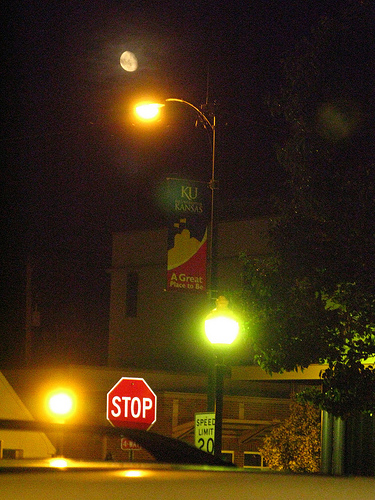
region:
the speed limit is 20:
[173, 407, 219, 471]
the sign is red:
[91, 376, 186, 477]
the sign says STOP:
[104, 354, 158, 444]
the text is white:
[106, 390, 170, 436]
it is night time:
[38, 127, 267, 487]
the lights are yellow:
[195, 289, 279, 388]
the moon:
[117, 40, 151, 73]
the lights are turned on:
[85, 75, 309, 406]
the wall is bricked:
[181, 403, 200, 420]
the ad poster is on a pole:
[159, 168, 221, 300]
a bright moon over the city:
[96, 37, 154, 74]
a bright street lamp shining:
[44, 392, 82, 467]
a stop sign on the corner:
[111, 365, 161, 446]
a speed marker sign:
[186, 401, 222, 455]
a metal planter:
[317, 414, 366, 481]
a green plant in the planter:
[307, 387, 357, 412]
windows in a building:
[236, 442, 267, 467]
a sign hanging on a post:
[165, 177, 219, 295]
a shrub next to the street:
[259, 410, 313, 471]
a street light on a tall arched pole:
[116, 89, 226, 151]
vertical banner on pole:
[159, 170, 216, 306]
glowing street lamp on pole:
[200, 302, 248, 356]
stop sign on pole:
[104, 373, 164, 456]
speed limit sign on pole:
[188, 406, 218, 458]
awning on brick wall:
[229, 415, 274, 445]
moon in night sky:
[108, 42, 144, 79]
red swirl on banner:
[163, 240, 208, 296]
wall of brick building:
[247, 405, 275, 414]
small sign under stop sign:
[113, 435, 146, 452]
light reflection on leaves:
[255, 335, 283, 373]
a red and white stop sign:
[104, 375, 158, 436]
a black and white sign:
[192, 411, 218, 457]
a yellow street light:
[201, 295, 243, 346]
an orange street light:
[36, 380, 87, 425]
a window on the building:
[121, 268, 141, 319]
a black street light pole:
[159, 93, 226, 466]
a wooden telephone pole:
[20, 249, 37, 371]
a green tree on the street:
[223, 0, 374, 437]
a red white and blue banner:
[163, 175, 211, 293]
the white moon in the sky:
[118, 48, 139, 72]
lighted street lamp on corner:
[113, 64, 259, 475]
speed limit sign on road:
[184, 396, 224, 473]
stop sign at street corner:
[91, 361, 169, 461]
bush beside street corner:
[258, 386, 352, 484]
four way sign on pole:
[114, 428, 145, 464]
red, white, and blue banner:
[146, 161, 214, 309]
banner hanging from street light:
[143, 150, 230, 331]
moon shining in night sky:
[89, 24, 157, 85]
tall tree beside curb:
[242, 9, 367, 455]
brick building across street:
[110, 383, 315, 469]